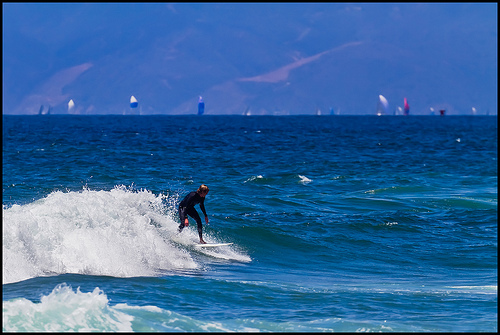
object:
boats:
[196, 95, 205, 116]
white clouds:
[296, 27, 311, 41]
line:
[195, 276, 499, 297]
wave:
[0, 176, 253, 285]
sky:
[0, 4, 495, 116]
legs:
[186, 207, 209, 244]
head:
[197, 184, 209, 198]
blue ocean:
[2, 114, 495, 334]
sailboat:
[376, 94, 390, 117]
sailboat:
[402, 97, 410, 116]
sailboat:
[129, 95, 139, 109]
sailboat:
[67, 99, 75, 113]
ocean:
[1, 114, 499, 334]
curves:
[339, 182, 500, 213]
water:
[1, 115, 499, 331]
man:
[176, 184, 209, 245]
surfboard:
[192, 242, 233, 247]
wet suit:
[177, 191, 209, 238]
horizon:
[0, 108, 498, 122]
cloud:
[10, 61, 96, 115]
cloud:
[228, 39, 364, 84]